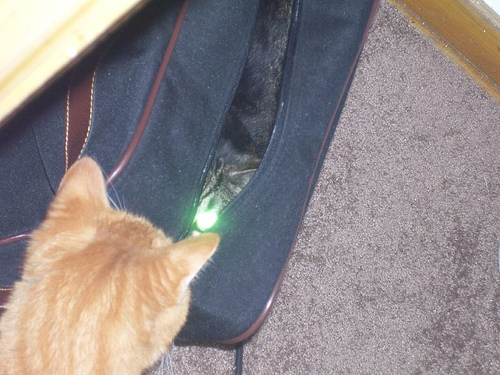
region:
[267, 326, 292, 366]
Small patch of brown carpet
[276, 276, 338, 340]
Small patch of brown carpet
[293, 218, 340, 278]
Small patch of brown carpet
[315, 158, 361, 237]
Small patch of brown carpet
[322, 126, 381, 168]
Small patch of brown carpet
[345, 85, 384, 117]
Small patch of brown carpet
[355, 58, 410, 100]
Small patch of brown carpet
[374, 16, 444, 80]
Small patch of brown carpet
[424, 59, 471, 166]
Small patch of brown carpet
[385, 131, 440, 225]
Small patch of brown carpet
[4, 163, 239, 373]
small brown head of cat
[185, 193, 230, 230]
green light in case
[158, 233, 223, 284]
orange and white ear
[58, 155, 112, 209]
orange and white ear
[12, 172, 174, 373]
orange and white head of cat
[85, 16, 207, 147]
brown and blue back back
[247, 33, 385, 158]
brown and blue bag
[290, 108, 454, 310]
blue carpet on the ground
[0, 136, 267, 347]
cat staring at light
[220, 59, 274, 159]
black inside of bag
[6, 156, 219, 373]
a rust colored cat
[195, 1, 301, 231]
a black cat inside of a bag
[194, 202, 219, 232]
green glowing eyes of cat in the bag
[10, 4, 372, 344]
blue suitcase with black cat inside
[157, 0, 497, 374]
gray carpet on the flor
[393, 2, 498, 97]
brown wood baseboard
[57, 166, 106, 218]
orange cat's left ear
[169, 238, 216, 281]
orange cat's right ear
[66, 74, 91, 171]
brown leather strip stitched on to bag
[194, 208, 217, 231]
reflection of camera light on eyes of black cat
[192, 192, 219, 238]
the light is on the bag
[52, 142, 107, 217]
the cat has a right ear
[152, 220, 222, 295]
the cat has a left ear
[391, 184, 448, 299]
the rug is gray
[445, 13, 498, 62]
the side of the wall is wooden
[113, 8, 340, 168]
the luggage is blue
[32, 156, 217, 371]
the cat is looking at the luggage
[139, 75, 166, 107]
the lining is purple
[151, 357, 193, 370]
the whiskers are white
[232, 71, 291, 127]
the zipper is open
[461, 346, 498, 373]
part of the carpeted floor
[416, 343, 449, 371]
part of the carpeted floor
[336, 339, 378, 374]
part of the carpeted floor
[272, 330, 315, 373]
part of the carpeted floor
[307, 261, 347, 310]
part of the carpeted floor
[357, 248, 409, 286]
part of the carpeted floor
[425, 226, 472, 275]
part of the carpeted floor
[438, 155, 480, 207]
part of the carpeted floor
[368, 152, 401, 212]
part of the carpeted floor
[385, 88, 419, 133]
part of the carpeted floor